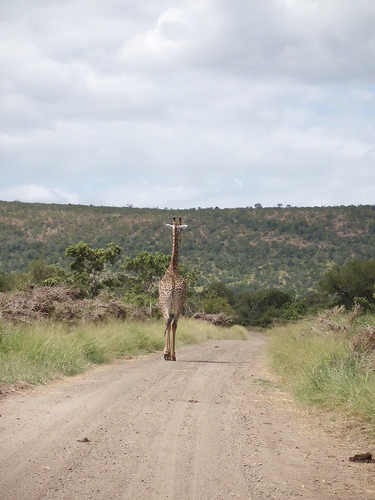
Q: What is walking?
A: A giraffe.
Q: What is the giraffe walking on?
A: The road.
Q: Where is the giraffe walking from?
A: The wilderness.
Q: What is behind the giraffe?
A: Trees.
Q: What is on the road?
A: An animal.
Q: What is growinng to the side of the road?
A: Grass.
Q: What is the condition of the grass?
A: Wild.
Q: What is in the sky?
A: Clouds.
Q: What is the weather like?
A: Cloudy.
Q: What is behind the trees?
A: Mountains.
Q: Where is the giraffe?
A: In the road.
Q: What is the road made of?
A: Dirt.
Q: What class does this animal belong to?
A: Mammal.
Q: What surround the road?
A: Grass.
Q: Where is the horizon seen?
A: Over the hill.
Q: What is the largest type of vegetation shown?
A: Trees.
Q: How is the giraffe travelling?
A: Walking.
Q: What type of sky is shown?
A: Cloudy.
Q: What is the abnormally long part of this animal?
A: Neck.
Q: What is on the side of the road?
A: Weeds.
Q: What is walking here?
A: Giraffe.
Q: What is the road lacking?
A: Being paved.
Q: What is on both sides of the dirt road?
A: Grass.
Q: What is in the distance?
A: Hill.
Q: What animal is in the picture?
A: A Giraffe.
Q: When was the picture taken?
A: Daytime.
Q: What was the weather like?
A: Cloudy.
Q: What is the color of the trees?
A: Green.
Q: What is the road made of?
A: Dirt.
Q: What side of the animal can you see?
A: Back.